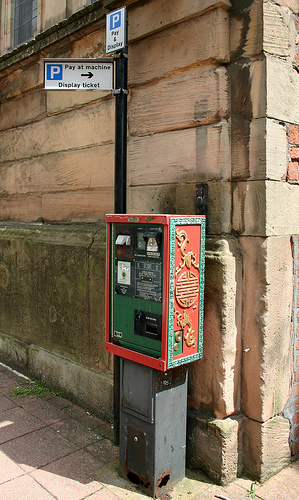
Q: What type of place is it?
A: It is a sidewalk.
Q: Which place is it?
A: It is a sidewalk.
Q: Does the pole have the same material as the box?
A: Yes, both the pole and the box are made of metal.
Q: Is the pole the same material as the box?
A: Yes, both the pole and the box are made of metal.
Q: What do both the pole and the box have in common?
A: The material, both the pole and the box are metallic.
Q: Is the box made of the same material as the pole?
A: Yes, both the box and the pole are made of metal.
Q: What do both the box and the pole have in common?
A: The material, both the box and the pole are metallic.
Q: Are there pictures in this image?
A: No, there are no pictures.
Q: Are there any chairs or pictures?
A: No, there are no pictures or chairs.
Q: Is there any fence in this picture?
A: No, there are no fences.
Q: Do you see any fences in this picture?
A: No, there are no fences.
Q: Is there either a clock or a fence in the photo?
A: No, there are no fences or clocks.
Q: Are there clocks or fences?
A: No, there are no fences or clocks.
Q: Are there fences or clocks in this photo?
A: No, there are no fences or clocks.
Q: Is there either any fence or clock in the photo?
A: No, there are no fences or clocks.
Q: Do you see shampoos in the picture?
A: No, there are no shampoos.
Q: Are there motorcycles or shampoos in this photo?
A: No, there are no shampoos or motorcycles.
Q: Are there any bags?
A: No, there are no bags.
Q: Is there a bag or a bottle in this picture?
A: No, there are no bags or bottles.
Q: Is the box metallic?
A: Yes, the box is metallic.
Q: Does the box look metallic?
A: Yes, the box is metallic.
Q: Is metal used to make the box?
A: Yes, the box is made of metal.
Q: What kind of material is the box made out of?
A: The box is made of metal.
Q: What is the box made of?
A: The box is made of metal.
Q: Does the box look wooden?
A: No, the box is metallic.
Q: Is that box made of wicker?
A: No, the box is made of metal.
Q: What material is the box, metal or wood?
A: The box is made of metal.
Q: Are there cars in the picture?
A: No, there are no cars.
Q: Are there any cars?
A: No, there are no cars.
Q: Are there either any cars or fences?
A: No, there are no cars or fences.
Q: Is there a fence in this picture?
A: No, there are no fences.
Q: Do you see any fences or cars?
A: No, there are no fences or cars.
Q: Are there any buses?
A: No, there are no buses.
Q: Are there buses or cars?
A: No, there are no buses or cars.